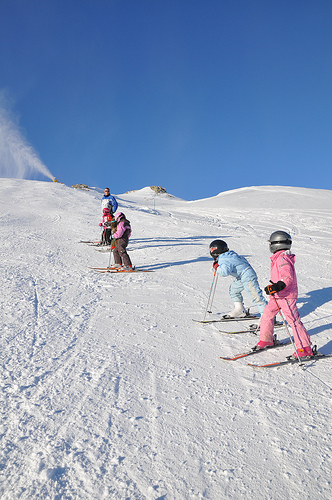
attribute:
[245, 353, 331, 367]
ski — long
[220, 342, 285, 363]
ski — long, snow covered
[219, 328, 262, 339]
ski — long, snow covered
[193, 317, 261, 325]
ski — long, snow covered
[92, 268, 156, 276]
ski — long, snow covered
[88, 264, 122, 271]
ski — long, snow covered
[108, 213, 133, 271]
child — skier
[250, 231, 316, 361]
child — skier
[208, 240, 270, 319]
child — skier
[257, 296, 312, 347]
snow pants — pink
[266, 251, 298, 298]
jacket — pink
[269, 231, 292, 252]
helmet — gray, silver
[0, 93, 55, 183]
snow — white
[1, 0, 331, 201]
sky — blue, cloudless, clear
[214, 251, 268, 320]
snowsuit — blue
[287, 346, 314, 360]
boot — pink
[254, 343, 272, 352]
boot — pink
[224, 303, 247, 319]
boot — white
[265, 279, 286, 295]
glove — black, red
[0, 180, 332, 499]
snow — packed down, white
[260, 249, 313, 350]
snowsuit — pink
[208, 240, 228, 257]
helmet — black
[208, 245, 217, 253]
logo — red